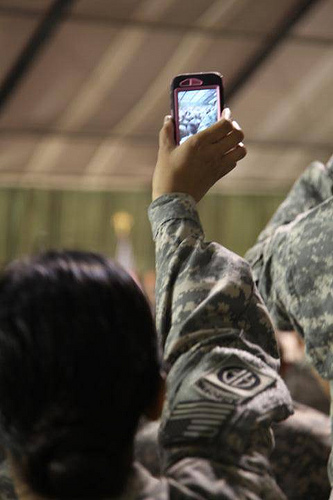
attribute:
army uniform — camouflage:
[1, 190, 294, 499]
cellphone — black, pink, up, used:
[170, 72, 223, 147]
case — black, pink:
[172, 70, 225, 148]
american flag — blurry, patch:
[160, 401, 238, 445]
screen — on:
[178, 89, 218, 138]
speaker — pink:
[178, 77, 201, 89]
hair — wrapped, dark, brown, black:
[0, 250, 162, 498]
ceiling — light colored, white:
[2, 0, 332, 195]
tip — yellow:
[111, 211, 135, 232]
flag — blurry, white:
[116, 237, 139, 282]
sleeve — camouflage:
[148, 192, 294, 499]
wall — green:
[1, 186, 285, 271]